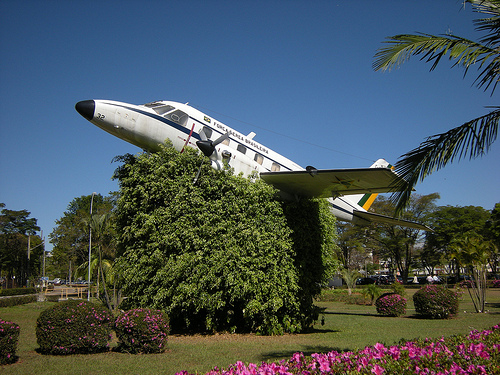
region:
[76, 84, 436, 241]
white airplane landed on tree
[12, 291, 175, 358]
small green bushes with pink flowers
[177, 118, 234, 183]
black and silver propeller of airplane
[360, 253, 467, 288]
cars in parking lot in the background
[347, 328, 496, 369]
small pink flowers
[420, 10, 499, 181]
green leaves of palm tree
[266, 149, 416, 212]
small wing of airplane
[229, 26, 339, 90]
bright sky with no clouds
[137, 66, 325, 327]
green bushy tree landed on by airplane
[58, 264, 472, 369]
well manicured garden area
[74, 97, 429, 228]
an airplane on display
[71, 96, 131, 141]
the nose of an airplane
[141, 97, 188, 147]
the cockpit of an airplane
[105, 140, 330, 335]
a large green bush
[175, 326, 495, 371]
purple flowers in bloom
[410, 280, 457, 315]
a green shrub with purple flowers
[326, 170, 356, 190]
a star on the underside of an airplane wing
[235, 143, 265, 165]
two windows on a plane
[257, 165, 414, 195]
the wing of a plane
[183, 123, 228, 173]
a plane engine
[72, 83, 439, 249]
Airplane on display resting on top of bush.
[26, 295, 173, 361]
Shrubs growing with purple flowers.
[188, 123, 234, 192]
Propeller on side of airplane.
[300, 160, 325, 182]
Light in front of airplane wing.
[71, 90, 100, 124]
Nose cone on airplane.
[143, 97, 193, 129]
Windows over cockpit area of plane.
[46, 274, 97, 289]
Cars parked in parking lot in distance.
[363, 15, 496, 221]
Fronds on a palm tree.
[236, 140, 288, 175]
Windows on side of airplane.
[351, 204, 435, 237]
Horizontal stabilizer in rear of plane.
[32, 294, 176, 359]
two bushes with pink blooms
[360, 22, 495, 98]
blue sky and palm tree frond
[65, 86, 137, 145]
nose cone of an airplane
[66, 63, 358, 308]
airplane behind a bush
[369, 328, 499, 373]
pink flowers and green foliage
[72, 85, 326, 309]
large bush in front of airplane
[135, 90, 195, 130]
front windshield of an airplane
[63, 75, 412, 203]
airplane and blue sky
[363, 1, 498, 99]
blue sky and palm fronds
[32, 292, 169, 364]
two neatly trimmed bushes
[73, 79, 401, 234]
a plane on a bush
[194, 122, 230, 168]
a propeller of a plane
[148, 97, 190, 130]
the front window of a plane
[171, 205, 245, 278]
the leaves of a bush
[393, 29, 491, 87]
the leaf of a palm tree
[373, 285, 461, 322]
bushes on a lawn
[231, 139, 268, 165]
the windows of a plane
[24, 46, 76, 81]
the clear blue sky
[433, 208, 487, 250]
the leaves of a tree